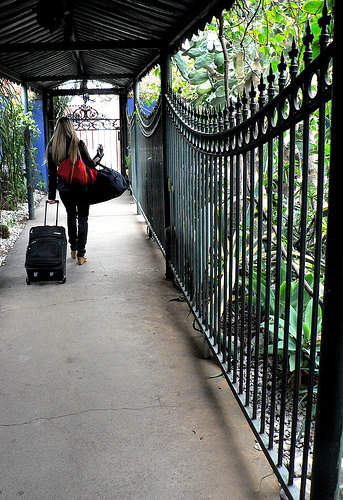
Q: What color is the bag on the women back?
A: Red.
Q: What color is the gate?
A: Black.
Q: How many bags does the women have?
A: 3.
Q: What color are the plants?
A: Green.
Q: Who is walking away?
A: The women.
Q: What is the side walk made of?
A: Concrete.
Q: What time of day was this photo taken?
A: Daytime.